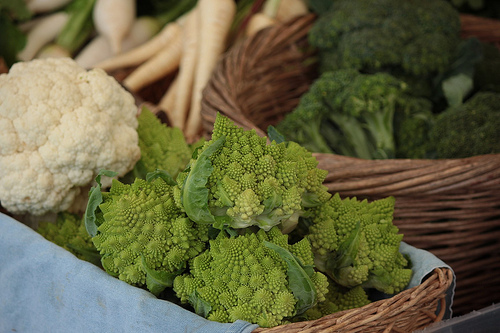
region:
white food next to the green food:
[6, 46, 147, 188]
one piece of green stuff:
[231, 186, 264, 216]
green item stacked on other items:
[193, 123, 328, 236]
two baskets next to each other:
[291, 145, 481, 328]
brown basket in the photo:
[401, 160, 483, 238]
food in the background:
[116, 13, 244, 83]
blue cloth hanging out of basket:
[408, 245, 450, 279]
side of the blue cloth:
[18, 257, 78, 317]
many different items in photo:
[16, 78, 450, 321]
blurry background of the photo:
[125, 5, 250, 70]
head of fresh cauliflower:
[2, 39, 129, 232]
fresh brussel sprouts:
[79, 120, 446, 302]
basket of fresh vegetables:
[0, 44, 434, 324]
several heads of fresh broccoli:
[256, 8, 498, 163]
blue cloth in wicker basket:
[2, 155, 473, 328]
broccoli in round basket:
[168, 25, 497, 290]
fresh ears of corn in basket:
[1, 3, 197, 81]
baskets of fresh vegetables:
[1, 2, 485, 328]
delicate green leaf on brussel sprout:
[178, 135, 323, 239]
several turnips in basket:
[145, 0, 223, 145]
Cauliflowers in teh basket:
[0, 38, 147, 207]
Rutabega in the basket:
[118, 5, 225, 127]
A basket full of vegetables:
[11, 92, 456, 327]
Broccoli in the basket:
[289, 69, 403, 144]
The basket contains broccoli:
[221, 11, 499, 218]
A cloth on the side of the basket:
[0, 207, 244, 331]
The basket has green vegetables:
[89, 121, 406, 288]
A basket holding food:
[2, 78, 453, 327]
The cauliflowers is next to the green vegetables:
[1, 42, 141, 214]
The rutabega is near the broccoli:
[118, 10, 238, 116]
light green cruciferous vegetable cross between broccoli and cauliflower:
[66, 125, 421, 320]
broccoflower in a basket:
[93, 143, 416, 328]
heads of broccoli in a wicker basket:
[247, 0, 494, 153]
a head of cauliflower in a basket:
[1, 53, 148, 203]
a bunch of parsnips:
[127, 0, 254, 128]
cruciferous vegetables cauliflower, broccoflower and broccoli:
[14, 25, 499, 325]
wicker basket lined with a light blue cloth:
[1, 265, 463, 331]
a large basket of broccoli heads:
[212, 7, 492, 165]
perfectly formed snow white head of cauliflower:
[1, 42, 144, 223]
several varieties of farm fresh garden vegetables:
[5, 7, 486, 327]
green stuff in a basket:
[151, 146, 316, 256]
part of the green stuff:
[223, 185, 264, 225]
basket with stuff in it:
[390, 278, 445, 320]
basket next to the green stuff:
[414, 156, 480, 221]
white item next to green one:
[24, 90, 114, 139]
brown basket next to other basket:
[431, 172, 480, 213]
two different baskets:
[391, 175, 481, 292]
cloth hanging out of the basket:
[418, 248, 453, 283]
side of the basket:
[261, 54, 300, 108]